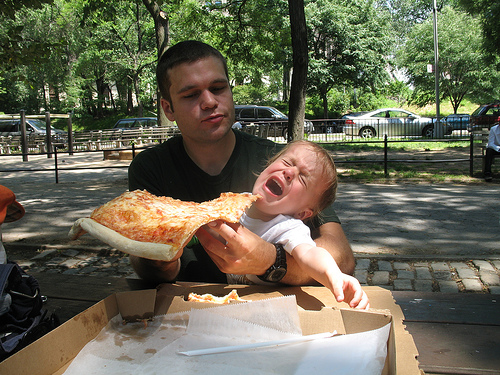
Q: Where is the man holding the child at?
A: In his arms.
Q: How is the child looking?
A: Very upset.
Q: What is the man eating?
A: Cheese pizza.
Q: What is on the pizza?
A: Lots of cheese.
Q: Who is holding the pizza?
A: The man.